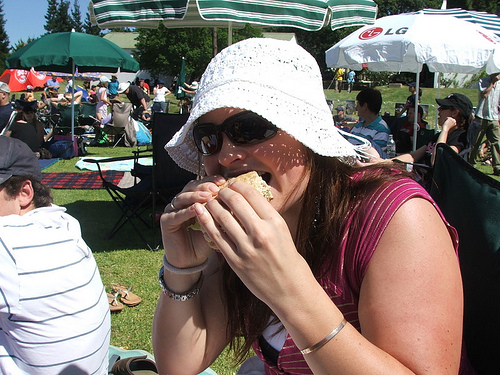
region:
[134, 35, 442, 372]
A woman eating somethings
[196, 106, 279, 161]
A woman wearing black color goggles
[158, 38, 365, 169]
A woman wearing white color hat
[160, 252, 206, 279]
A woman wearing wristband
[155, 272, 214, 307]
A woman wearing wrist watch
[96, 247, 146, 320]
Green color grass with pair of chapples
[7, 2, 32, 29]
A blue color sky with clouds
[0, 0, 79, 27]
Tree with green leaves and branches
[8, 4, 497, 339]
Lot of peoples sitting in the chairs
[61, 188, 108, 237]
Shadow of the tent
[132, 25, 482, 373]
mid-20s, mid-size, middle-brown haired, tanned armed woman eating a sandwich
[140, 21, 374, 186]
bucket hat, in white lace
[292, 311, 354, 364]
thin silvertone bracelet, maybe silver even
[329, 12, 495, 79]
of course it's an advertising umbrella. until recently, people would be EMBARRASSED to advertise carp @ music festivals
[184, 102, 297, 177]
big black sunglasses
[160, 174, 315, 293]
nice big hands, long fingers, no nail polish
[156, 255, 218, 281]
bracelet woven or twisted or elsewise constructed of fabric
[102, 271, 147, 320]
two brown leather soled sandals, abandoned on the grass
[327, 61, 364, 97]
two tiny people walking together, the taller in a yellow shirt & the smaller in pastel blue, all the way in the back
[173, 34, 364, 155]
The woman is wearing a hat.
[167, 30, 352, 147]
The woman's hat is white.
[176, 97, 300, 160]
The woman is wearing glasses.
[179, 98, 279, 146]
The woman's glasses are dark.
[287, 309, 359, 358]
The woman is wearing a bracelet.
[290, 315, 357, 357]
The woman's bracelet is silver.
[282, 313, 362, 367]
The woman's bracelet is shiny.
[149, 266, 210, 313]
The woman is wearing a bracelet.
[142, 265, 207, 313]
The woman's bracelet has square links.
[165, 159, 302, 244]
The woman is eating a sandwich.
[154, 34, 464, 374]
A lady in a white hat.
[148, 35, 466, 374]
A woman eating a sandwich.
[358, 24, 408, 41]
The LG logo.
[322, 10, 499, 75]
A white umbrella with an LG logo.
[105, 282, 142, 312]
A pair of slippers in the grass.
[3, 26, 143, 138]
A green umbrella.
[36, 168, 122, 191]
A red and black plaid blanket.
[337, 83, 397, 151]
A gentleman in a blue striped shirt.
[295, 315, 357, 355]
A silver bracelet.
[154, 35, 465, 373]
A woman wearing sunglasses.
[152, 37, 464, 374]
woman eating a sandwhich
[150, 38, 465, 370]
woman wearing a white hat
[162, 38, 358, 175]
white hat on the woman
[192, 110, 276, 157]
black sunglasses on the woman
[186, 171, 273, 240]
sandwhich in the woman's hands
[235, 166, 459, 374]
pink shirt on the woman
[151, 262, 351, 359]
silver bracelets on the woman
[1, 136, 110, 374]
man wearing a black hat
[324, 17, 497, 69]
white umbrella over the people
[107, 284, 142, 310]
pair of sandals in the grass